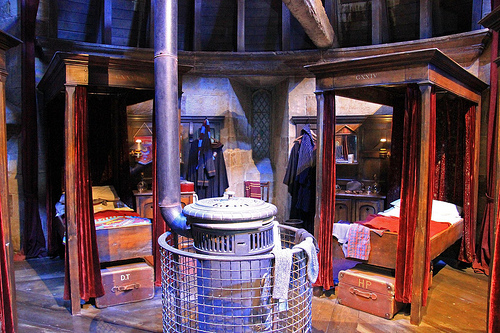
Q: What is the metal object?
A: Heater.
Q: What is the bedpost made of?
A: Wood.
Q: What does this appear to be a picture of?
A: Stage.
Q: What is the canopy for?
A: Bed.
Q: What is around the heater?
A: Fence.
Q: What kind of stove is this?
A: Wood burning.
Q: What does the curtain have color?
A: Red.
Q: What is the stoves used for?
A: Heating.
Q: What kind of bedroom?
A: Open loft type.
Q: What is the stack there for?
A: Stove.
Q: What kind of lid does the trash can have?
A: Metal lid.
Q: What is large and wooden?
A: The support pole.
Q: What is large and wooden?
A: The bed structure.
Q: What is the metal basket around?
A: The trash can.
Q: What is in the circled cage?
A: A wooden heater.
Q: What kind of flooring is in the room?
A: Hardwood.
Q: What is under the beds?
A: Suitcases.